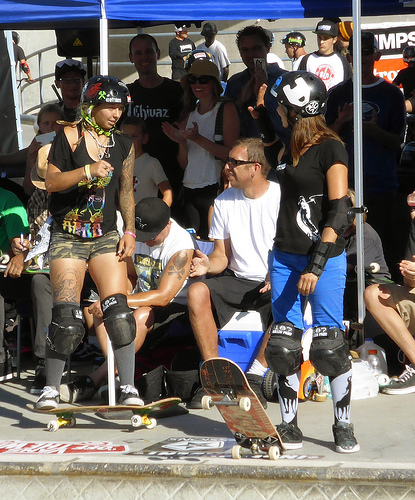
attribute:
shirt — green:
[1, 188, 33, 255]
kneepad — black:
[307, 327, 353, 378]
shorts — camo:
[42, 228, 126, 260]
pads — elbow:
[314, 192, 357, 248]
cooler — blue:
[220, 329, 258, 363]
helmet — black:
[82, 72, 132, 104]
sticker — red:
[96, 88, 106, 99]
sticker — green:
[82, 80, 102, 100]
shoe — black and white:
[380, 342, 412, 404]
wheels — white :
[199, 388, 249, 414]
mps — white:
[380, 28, 414, 51]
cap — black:
[311, 18, 344, 34]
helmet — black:
[266, 68, 329, 118]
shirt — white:
[252, 124, 332, 273]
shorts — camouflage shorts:
[31, 227, 124, 267]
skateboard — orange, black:
[198, 355, 287, 456]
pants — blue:
[267, 243, 346, 335]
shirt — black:
[272, 130, 347, 258]